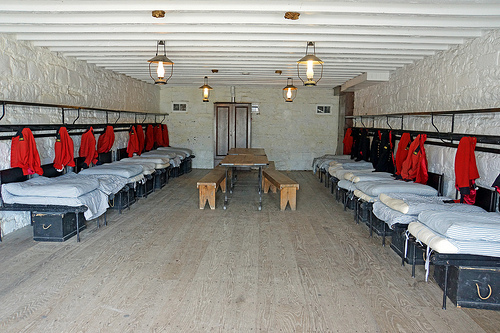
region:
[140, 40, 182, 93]
light bulb coming from ceiling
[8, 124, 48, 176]
red jacket on the wall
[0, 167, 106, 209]
bed in the room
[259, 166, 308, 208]
brown bench in middle of floor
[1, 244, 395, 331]
the floor in the room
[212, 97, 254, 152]
brown door in gthe room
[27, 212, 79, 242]
black dresser under bed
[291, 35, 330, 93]
a lamp hanging from ceiling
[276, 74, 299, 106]
a lamp hanging from ceiling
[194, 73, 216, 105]
a lamp hanging from ceiling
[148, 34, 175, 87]
a lamp hanging from ceiling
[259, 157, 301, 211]
a bench color brown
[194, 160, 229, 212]
a bench color brown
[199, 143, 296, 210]
two tables in middle of benches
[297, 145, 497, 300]
folded beads on side the room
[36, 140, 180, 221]
folded beads on side the room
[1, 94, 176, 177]
long hanger with red clothes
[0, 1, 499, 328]
a fireman's sleeping quarters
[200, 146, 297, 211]
tables and benches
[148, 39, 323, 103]
oil lamps hanging from the ceiling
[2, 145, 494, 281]
beds along the walls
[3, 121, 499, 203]
uniforms hanging from hooks on the walls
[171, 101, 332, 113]
air conditioning registers on the rear wall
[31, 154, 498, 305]
storage trunks under the beds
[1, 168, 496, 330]
a polished wooden floor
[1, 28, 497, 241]
white hewn stone walls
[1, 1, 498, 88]
white painted wooden cross beams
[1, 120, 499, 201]
RED ROBES HANGING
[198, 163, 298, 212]
the wooden benches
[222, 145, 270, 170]
the wood tables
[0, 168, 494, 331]
the oak floor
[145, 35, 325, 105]
lights in the ceiling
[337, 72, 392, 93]
vent in ceiling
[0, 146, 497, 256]
white pillows folded down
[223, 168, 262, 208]
the legs on the table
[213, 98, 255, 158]
a chest on wall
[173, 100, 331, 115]
vents on the wall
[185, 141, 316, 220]
benches around a table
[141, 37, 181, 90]
light fixture hanging on the ceiling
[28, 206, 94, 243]
black trunk on the floor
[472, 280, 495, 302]
handle on the trunk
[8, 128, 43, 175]
red fabric hanging on the wall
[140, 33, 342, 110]
four light fixtures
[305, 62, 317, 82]
the light bulb is on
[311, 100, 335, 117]
vent high on the wall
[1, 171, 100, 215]
mattress folded in half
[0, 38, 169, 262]
the wall is textured